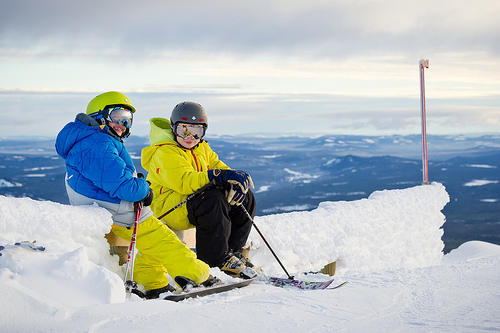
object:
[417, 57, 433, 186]
pole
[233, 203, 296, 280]
ski pole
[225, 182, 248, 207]
hand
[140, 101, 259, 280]
people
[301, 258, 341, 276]
skis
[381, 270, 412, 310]
footprints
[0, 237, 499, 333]
ground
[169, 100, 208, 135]
helmet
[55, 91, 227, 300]
child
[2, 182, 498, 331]
snow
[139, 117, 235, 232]
jacket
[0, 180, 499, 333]
snow mound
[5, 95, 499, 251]
mountain range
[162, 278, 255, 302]
skis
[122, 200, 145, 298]
ski pole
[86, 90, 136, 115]
helmet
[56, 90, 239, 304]
man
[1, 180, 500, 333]
slope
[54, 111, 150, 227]
jacket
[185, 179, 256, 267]
pants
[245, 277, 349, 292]
skis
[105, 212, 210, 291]
pants